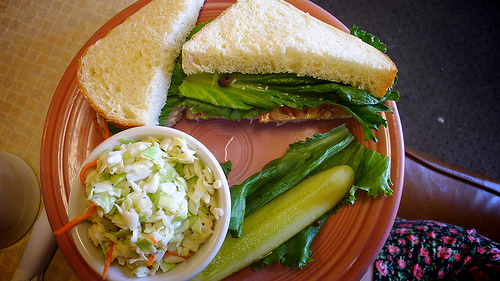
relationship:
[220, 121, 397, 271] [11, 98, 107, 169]
lettuce on plate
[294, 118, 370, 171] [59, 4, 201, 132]
lettuce in sandwich